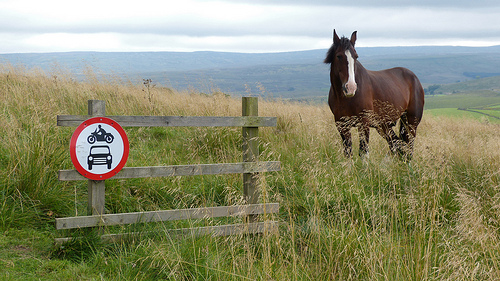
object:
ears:
[345, 30, 365, 48]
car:
[87, 145, 113, 171]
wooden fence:
[55, 93, 280, 238]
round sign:
[68, 114, 127, 178]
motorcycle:
[86, 123, 115, 145]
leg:
[332, 117, 354, 161]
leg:
[357, 125, 370, 155]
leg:
[372, 126, 398, 155]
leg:
[400, 117, 414, 160]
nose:
[340, 79, 360, 102]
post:
[83, 96, 113, 245]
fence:
[46, 86, 287, 253]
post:
[55, 114, 278, 128]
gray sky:
[4, 1, 497, 49]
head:
[320, 31, 364, 99]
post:
[241, 96, 263, 243]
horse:
[322, 27, 427, 169]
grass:
[0, 96, 499, 281]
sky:
[1, 0, 499, 55]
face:
[342, 50, 355, 93]